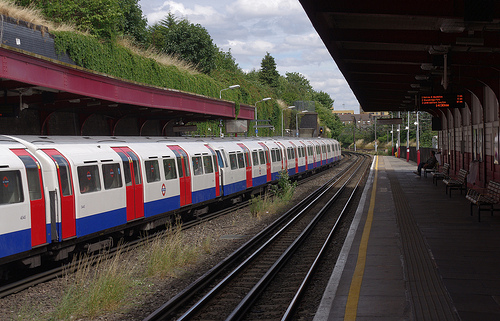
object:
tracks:
[137, 149, 370, 320]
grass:
[45, 251, 145, 320]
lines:
[313, 155, 379, 320]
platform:
[310, 153, 498, 320]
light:
[263, 96, 271, 103]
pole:
[253, 95, 273, 139]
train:
[0, 133, 345, 272]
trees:
[17, 0, 220, 74]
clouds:
[137, 0, 358, 115]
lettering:
[421, 94, 451, 107]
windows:
[76, 161, 123, 193]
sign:
[414, 91, 466, 109]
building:
[339, 112, 376, 129]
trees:
[245, 53, 338, 107]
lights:
[398, 23, 465, 103]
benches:
[421, 156, 498, 221]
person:
[411, 149, 437, 177]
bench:
[422, 160, 442, 178]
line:
[344, 140, 378, 320]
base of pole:
[416, 149, 421, 166]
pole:
[414, 111, 421, 151]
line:
[310, 155, 376, 319]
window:
[0, 167, 26, 207]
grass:
[250, 176, 295, 219]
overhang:
[0, 45, 257, 136]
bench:
[441, 166, 467, 195]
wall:
[437, 83, 500, 189]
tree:
[256, 50, 281, 89]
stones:
[5, 291, 50, 320]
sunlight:
[371, 152, 418, 173]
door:
[111, 144, 146, 221]